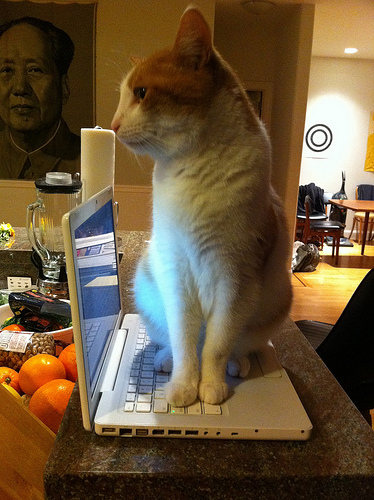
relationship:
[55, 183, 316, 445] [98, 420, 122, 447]
laptop has port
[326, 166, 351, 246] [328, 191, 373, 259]
vacuum behind dining room table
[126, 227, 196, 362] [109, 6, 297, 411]
reflection on side of cat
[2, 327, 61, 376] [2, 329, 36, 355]
bag has label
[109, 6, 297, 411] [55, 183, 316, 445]
cat sitting on laptop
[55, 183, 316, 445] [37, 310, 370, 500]
laptop on top of counter top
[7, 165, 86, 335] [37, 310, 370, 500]
blender on top of counter top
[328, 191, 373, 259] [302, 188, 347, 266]
dining room table has chair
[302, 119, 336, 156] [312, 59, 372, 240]
target on surface of wall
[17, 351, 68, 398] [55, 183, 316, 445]
orange by laptop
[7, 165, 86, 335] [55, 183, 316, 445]
blender behind laptop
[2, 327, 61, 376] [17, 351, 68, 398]
bag by orange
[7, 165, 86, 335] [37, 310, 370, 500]
blender sitting on counter top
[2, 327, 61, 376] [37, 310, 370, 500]
bag on top of counter top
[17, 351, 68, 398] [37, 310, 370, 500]
orange on top of counter top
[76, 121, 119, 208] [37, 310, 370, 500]
paper towels on top of counter top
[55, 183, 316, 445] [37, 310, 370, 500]
laptop sitting on counter top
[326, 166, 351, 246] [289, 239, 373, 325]
vacuum on floor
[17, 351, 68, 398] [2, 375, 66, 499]
orange inside of basket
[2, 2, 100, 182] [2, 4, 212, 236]
portrait hanging on wall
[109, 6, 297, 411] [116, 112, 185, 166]
cat has whiskers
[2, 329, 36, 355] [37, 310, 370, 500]
label on top of counter top